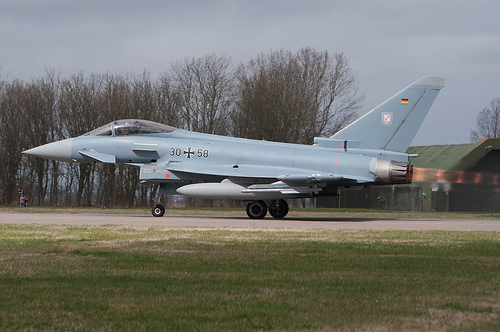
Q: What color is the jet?
A: Grey.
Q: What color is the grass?
A: Green.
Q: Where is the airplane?
A: On the runway.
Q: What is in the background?
A: Trees.